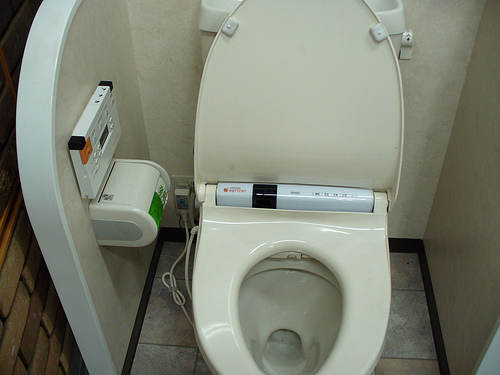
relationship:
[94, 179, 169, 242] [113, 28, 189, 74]
dispenser on wall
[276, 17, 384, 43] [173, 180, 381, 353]
lid of toilet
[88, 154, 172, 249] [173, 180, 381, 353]
dispenser behind toilet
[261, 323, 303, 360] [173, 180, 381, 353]
hole in toilet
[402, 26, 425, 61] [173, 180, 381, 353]
flusher on toilet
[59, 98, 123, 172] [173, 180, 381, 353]
control board near toilet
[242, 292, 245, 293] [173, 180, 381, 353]
water of toilet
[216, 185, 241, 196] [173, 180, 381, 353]
numbers on toilet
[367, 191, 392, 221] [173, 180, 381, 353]
hinge of toilet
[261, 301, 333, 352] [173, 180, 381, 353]
bowl of toilet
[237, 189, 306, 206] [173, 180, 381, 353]
electronics on toilet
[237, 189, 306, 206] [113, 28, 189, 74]
electronics on wall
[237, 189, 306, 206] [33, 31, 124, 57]
electronics on stall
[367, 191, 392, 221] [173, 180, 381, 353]
hinge on toilet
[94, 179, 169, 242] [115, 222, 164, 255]
dispenser of toilet paper